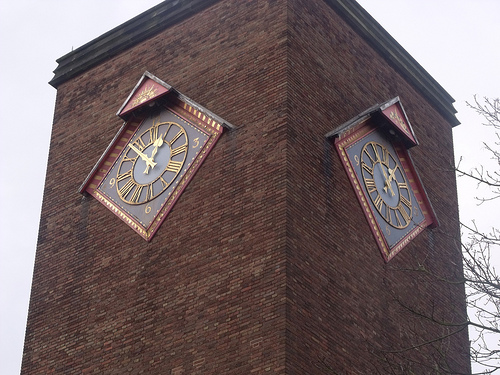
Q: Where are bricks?
A: On a building.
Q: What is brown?
A: Bricks.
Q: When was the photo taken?
A: Daytime.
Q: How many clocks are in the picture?
A: Two.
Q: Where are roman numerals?
A: On two clocks.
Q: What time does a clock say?
A: 12:54.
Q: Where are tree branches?
A: On the right.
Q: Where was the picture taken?
A: Beside this brick building.